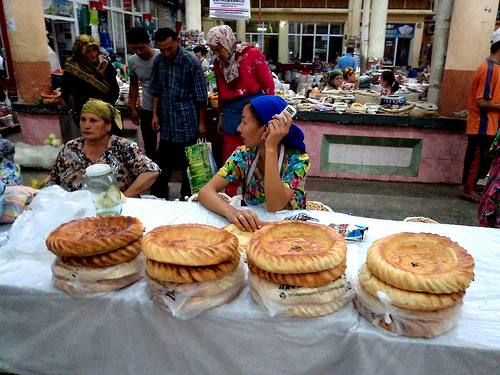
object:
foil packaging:
[297, 101, 314, 112]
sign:
[207, 0, 249, 20]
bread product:
[366, 230, 479, 293]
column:
[0, 0, 54, 105]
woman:
[60, 35, 120, 137]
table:
[1, 181, 497, 374]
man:
[146, 26, 206, 200]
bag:
[175, 65, 198, 109]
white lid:
[84, 163, 110, 177]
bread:
[244, 220, 346, 273]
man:
[457, 39, 499, 204]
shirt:
[462, 58, 499, 136]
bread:
[140, 222, 239, 266]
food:
[290, 88, 430, 115]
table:
[295, 107, 471, 183]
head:
[238, 92, 294, 150]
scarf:
[248, 94, 308, 152]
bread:
[44, 212, 137, 257]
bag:
[8, 187, 89, 248]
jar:
[80, 162, 123, 216]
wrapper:
[48, 260, 141, 304]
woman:
[50, 97, 161, 197]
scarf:
[80, 97, 122, 130]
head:
[80, 98, 112, 138]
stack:
[243, 219, 352, 319]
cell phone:
[276, 105, 299, 124]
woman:
[196, 94, 301, 236]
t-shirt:
[124, 49, 157, 113]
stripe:
[136, 71, 154, 85]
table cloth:
[0, 189, 499, 375]